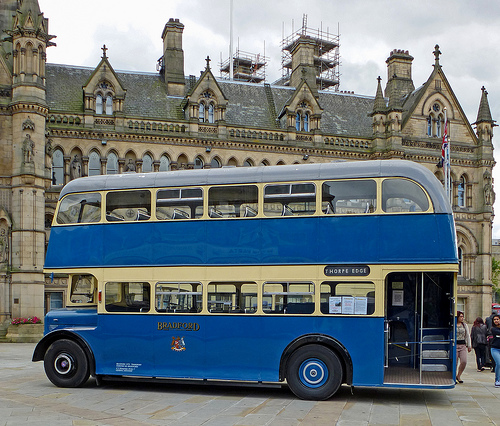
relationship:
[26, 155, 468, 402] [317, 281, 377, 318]
bus has window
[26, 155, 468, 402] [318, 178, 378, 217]
bus has window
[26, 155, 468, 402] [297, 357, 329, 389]
bus has hubcap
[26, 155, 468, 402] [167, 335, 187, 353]
bus has logo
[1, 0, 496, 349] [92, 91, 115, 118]
building has window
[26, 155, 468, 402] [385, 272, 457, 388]
bus has door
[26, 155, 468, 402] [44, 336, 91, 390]
bus has front wheel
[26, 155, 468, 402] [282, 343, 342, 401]
bus has back wheel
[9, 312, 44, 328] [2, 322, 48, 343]
flower growing inside planter box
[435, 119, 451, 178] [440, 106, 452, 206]
flag hanging on pole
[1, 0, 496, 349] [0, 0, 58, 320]
building has spire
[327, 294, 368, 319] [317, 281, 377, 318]
paper attached to window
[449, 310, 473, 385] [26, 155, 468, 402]
person next to bus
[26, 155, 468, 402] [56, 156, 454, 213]
bus has roof